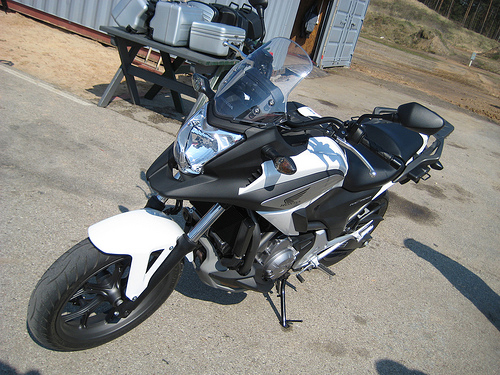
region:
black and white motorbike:
[41, 36, 452, 343]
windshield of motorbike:
[215, 37, 317, 119]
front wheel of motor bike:
[27, 221, 159, 353]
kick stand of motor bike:
[274, 286, 299, 338]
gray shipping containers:
[292, 0, 374, 64]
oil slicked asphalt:
[391, 206, 493, 360]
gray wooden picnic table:
[88, 31, 228, 97]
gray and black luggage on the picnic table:
[100, 0, 267, 61]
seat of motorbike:
[339, 111, 425, 191]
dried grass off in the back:
[374, 4, 470, 54]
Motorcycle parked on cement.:
[32, 60, 499, 342]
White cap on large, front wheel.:
[86, 214, 176, 314]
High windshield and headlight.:
[173, 43, 306, 172]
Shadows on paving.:
[3, 237, 496, 374]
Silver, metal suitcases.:
[115, 3, 252, 61]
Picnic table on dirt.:
[21, 11, 281, 121]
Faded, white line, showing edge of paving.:
[7, 63, 95, 130]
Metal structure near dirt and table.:
[25, 1, 400, 82]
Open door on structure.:
[292, 5, 335, 85]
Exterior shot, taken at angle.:
[5, 18, 492, 372]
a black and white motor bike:
[5, 44, 453, 359]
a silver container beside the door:
[326, 20, 364, 66]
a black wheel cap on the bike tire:
[57, 292, 128, 324]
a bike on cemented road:
[357, 305, 418, 330]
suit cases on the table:
[107, 2, 237, 61]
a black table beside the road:
[108, 21, 169, 110]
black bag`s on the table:
[223, 5, 260, 30]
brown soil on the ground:
[36, 34, 73, 73]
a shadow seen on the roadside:
[410, 231, 485, 302]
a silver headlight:
[177, 97, 237, 178]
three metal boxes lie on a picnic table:
[109, 4, 230, 49]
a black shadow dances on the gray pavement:
[406, 236, 498, 331]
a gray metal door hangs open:
[273, 4, 371, 63]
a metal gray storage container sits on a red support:
[23, 0, 97, 31]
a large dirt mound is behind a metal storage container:
[377, 2, 439, 51]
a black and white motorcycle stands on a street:
[29, 61, 461, 352]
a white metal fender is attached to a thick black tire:
[20, 204, 182, 366]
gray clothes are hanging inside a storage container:
[298, 3, 325, 38]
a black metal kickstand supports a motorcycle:
[277, 276, 299, 341]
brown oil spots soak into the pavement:
[331, 332, 366, 362]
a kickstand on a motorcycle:
[272, 266, 298, 331]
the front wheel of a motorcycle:
[22, 201, 199, 359]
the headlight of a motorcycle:
[168, 99, 249, 187]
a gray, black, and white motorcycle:
[20, 32, 460, 353]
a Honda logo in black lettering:
[275, 184, 315, 212]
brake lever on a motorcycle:
[318, 126, 381, 181]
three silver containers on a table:
[107, 1, 249, 66]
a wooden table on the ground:
[95, 18, 247, 131]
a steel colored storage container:
[0, 0, 374, 77]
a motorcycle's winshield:
[208, 30, 320, 140]